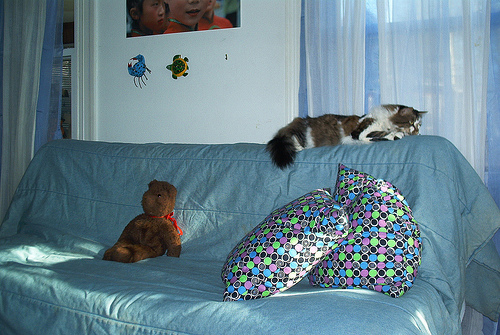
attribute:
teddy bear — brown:
[101, 178, 184, 265]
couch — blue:
[1, 135, 499, 334]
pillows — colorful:
[220, 163, 424, 303]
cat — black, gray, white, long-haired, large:
[266, 102, 428, 171]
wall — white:
[99, 1, 289, 147]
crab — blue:
[125, 52, 152, 88]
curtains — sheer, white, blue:
[305, 2, 485, 182]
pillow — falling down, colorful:
[220, 186, 350, 300]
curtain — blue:
[40, 0, 67, 154]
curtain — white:
[2, 0, 47, 216]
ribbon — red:
[153, 212, 183, 238]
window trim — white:
[74, 0, 100, 139]